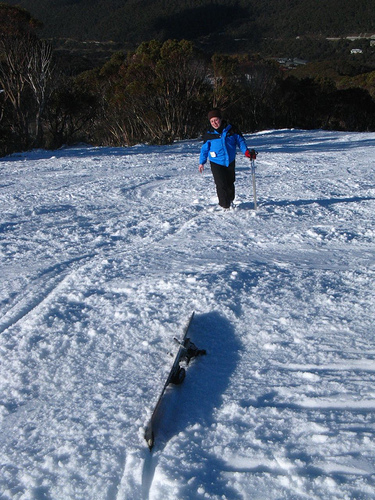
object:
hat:
[208, 109, 220, 119]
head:
[208, 109, 222, 129]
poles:
[251, 160, 257, 208]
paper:
[210, 152, 216, 158]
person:
[199, 110, 257, 208]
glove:
[245, 149, 258, 159]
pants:
[210, 160, 235, 208]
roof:
[294, 58, 304, 63]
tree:
[323, 89, 372, 131]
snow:
[0, 129, 373, 498]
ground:
[0, 126, 375, 498]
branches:
[165, 86, 172, 131]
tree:
[211, 54, 280, 134]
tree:
[0, 39, 55, 149]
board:
[144, 309, 195, 448]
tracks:
[0, 255, 94, 334]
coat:
[200, 123, 247, 167]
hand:
[199, 165, 204, 173]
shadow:
[2, 135, 375, 161]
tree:
[100, 39, 211, 147]